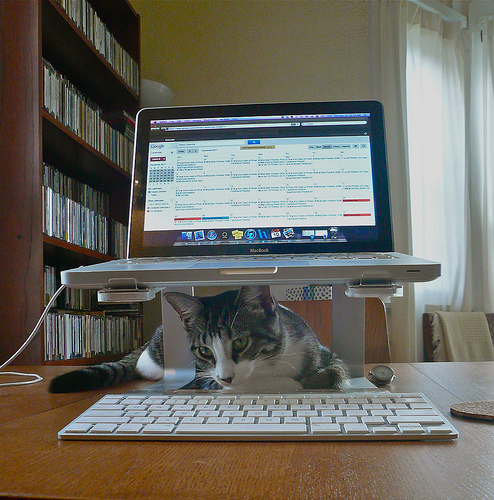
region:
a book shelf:
[3, 0, 149, 360]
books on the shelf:
[34, 63, 140, 168]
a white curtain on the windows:
[384, 9, 491, 316]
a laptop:
[72, 111, 432, 286]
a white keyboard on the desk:
[68, 393, 454, 438]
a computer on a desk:
[56, 104, 463, 445]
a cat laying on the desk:
[101, 298, 412, 389]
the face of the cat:
[178, 295, 276, 383]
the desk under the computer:
[22, 446, 471, 481]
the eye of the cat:
[231, 334, 247, 348]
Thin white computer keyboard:
[54, 389, 458, 437]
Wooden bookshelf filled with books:
[0, 1, 142, 362]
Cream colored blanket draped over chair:
[422, 310, 492, 359]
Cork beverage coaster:
[451, 401, 492, 417]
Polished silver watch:
[366, 361, 394, 384]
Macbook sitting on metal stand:
[62, 102, 439, 389]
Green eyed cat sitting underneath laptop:
[60, 106, 439, 390]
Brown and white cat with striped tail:
[53, 286, 347, 392]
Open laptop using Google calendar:
[61, 101, 442, 287]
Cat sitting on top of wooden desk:
[0, 281, 492, 498]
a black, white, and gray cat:
[46, 284, 349, 394]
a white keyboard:
[56, 390, 457, 441]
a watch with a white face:
[369, 364, 395, 385]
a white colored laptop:
[59, 98, 441, 287]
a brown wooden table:
[3, 358, 488, 497]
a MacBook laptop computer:
[60, 98, 439, 288]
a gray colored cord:
[1, 288, 63, 388]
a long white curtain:
[370, 0, 491, 362]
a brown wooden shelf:
[1, 0, 141, 366]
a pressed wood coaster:
[450, 399, 493, 422]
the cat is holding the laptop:
[104, 62, 458, 433]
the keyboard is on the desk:
[55, 381, 452, 469]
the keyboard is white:
[90, 372, 474, 496]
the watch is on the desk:
[362, 353, 424, 427]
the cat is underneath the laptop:
[141, 283, 454, 452]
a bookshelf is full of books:
[22, 15, 192, 360]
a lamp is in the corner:
[117, 62, 227, 149]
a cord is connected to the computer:
[8, 280, 168, 355]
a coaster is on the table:
[431, 378, 486, 416]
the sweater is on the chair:
[400, 299, 479, 367]